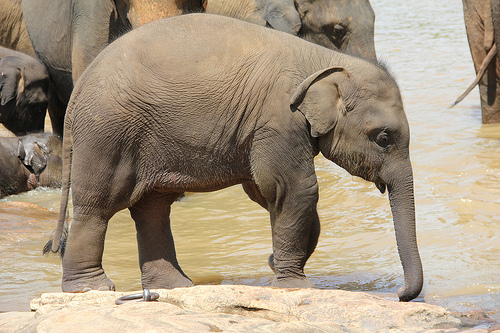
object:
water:
[0, 0, 500, 332]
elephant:
[1, 47, 49, 137]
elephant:
[203, 0, 379, 66]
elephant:
[43, 12, 425, 303]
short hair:
[16, 129, 63, 143]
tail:
[41, 75, 88, 259]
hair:
[43, 226, 69, 261]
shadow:
[189, 271, 426, 304]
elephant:
[450, 0, 500, 124]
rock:
[0, 271, 500, 333]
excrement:
[115, 287, 160, 304]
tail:
[450, 42, 496, 109]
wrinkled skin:
[72, 43, 313, 222]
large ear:
[288, 66, 355, 138]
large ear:
[263, 0, 302, 37]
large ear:
[0, 56, 25, 105]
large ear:
[17, 136, 51, 174]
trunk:
[377, 156, 424, 302]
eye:
[382, 135, 388, 142]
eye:
[334, 28, 341, 36]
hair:
[358, 55, 397, 78]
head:
[317, 50, 413, 194]